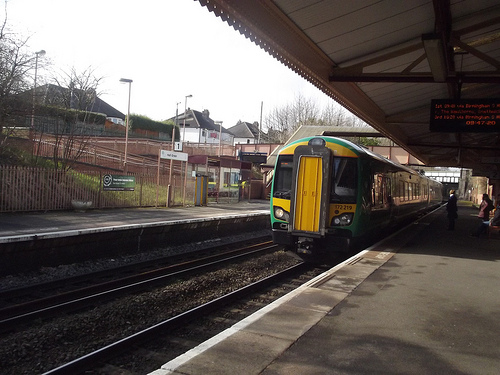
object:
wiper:
[276, 189, 290, 196]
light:
[310, 137, 324, 145]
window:
[277, 160, 294, 192]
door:
[293, 156, 323, 231]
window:
[433, 183, 440, 198]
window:
[415, 184, 420, 198]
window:
[406, 183, 413, 200]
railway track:
[43, 261, 309, 374]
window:
[397, 178, 404, 202]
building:
[225, 119, 282, 146]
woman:
[477, 193, 494, 223]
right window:
[326, 156, 359, 204]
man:
[443, 186, 456, 233]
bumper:
[269, 229, 349, 252]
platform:
[147, 199, 499, 374]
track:
[42, 261, 307, 374]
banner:
[102, 174, 137, 191]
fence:
[0, 164, 197, 212]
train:
[267, 122, 499, 267]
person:
[445, 186, 459, 234]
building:
[158, 107, 235, 147]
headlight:
[333, 218, 342, 226]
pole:
[167, 125, 175, 209]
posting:
[159, 149, 187, 161]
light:
[273, 209, 285, 219]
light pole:
[123, 81, 131, 168]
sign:
[429, 99, 498, 132]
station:
[1, 0, 496, 365]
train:
[269, 134, 448, 259]